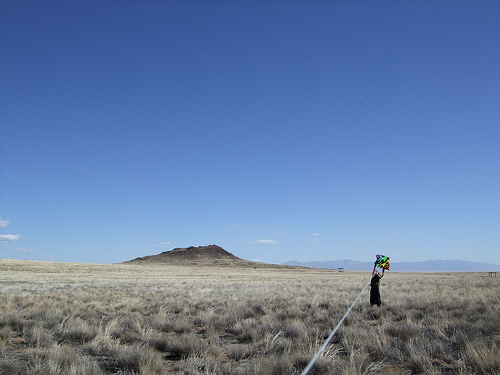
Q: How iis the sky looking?
A: Very blue.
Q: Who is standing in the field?
A: A person.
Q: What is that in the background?
A: A hill.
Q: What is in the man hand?
A: A kite.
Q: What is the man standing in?
A: Some dried weeds.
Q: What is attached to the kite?
A: A white string.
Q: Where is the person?
A: In a field.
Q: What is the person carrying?
A: A kite.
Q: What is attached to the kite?
A: A string.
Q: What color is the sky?
A: Bright blue.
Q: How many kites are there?
A: One.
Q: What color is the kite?
A: Yellow, green, and red.